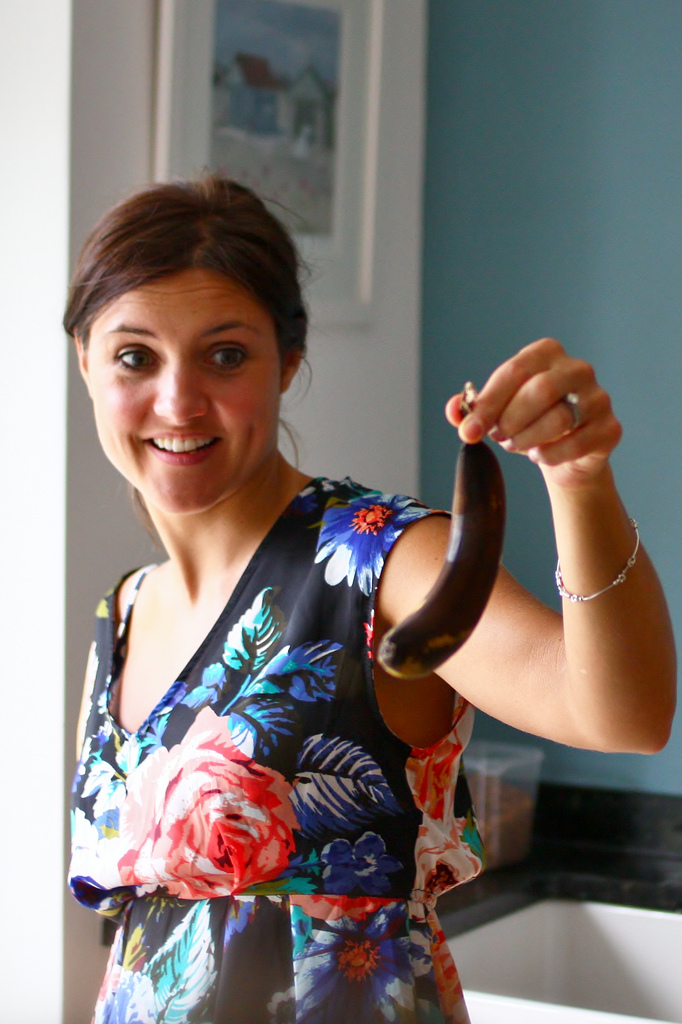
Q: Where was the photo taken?
A: In a kitchen.